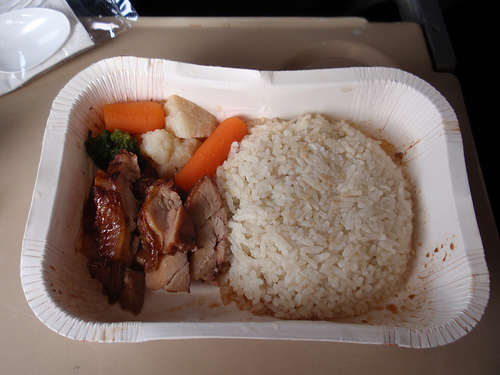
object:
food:
[75, 93, 415, 321]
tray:
[0, 16, 499, 374]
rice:
[214, 112, 414, 320]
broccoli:
[84, 128, 147, 170]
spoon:
[0, 8, 70, 76]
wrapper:
[75, 0, 141, 43]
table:
[0, 15, 499, 374]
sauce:
[394, 150, 403, 166]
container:
[20, 56, 491, 349]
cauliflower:
[139, 94, 219, 180]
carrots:
[174, 117, 246, 192]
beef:
[81, 149, 228, 320]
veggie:
[83, 128, 142, 171]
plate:
[18, 57, 494, 350]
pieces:
[127, 179, 199, 293]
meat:
[81, 148, 228, 320]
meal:
[77, 94, 414, 320]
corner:
[152, 90, 173, 101]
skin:
[92, 178, 117, 207]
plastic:
[70, 0, 138, 45]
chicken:
[107, 149, 141, 183]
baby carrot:
[103, 102, 165, 135]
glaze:
[102, 163, 141, 180]